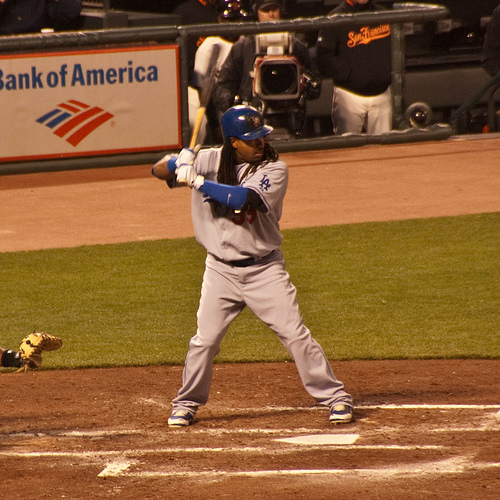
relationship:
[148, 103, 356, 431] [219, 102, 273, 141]
man wearing helmet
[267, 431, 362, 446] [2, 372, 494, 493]
base on baseball diamond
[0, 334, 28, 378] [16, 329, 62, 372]
catcher wearing glove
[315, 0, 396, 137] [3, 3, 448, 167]
man standing in dugout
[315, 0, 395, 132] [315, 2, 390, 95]
man wearing jacket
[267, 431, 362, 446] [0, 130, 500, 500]
base on baseball field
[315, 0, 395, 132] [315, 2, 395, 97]
man wearing jacket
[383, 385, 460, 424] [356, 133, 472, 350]
chalk in field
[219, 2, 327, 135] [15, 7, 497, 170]
cameraman in dugout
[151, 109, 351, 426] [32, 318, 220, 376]
man playing baseball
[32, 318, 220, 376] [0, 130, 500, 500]
baseball on baseball field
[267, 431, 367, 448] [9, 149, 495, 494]
base on baseball field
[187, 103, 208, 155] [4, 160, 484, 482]
bat being swung field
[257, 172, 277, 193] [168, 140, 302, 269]
words on shirt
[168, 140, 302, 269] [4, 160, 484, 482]
shirt on field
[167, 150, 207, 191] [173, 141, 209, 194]
gloves on hand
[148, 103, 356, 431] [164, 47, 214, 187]
man holding bat